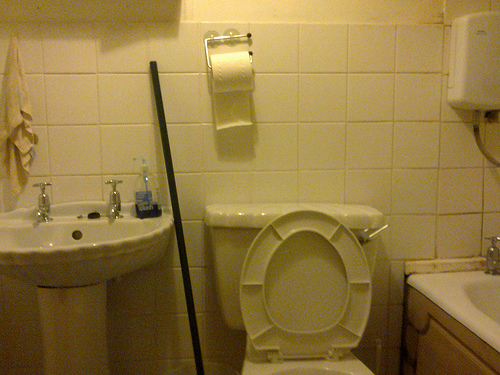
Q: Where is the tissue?
A: The wall.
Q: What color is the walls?
A: White.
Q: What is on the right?
A: The tub.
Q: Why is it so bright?
A: Lights are on.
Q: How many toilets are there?
A: One.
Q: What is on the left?
A: The sink.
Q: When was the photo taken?
A: Night time.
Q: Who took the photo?
A: The photographer.